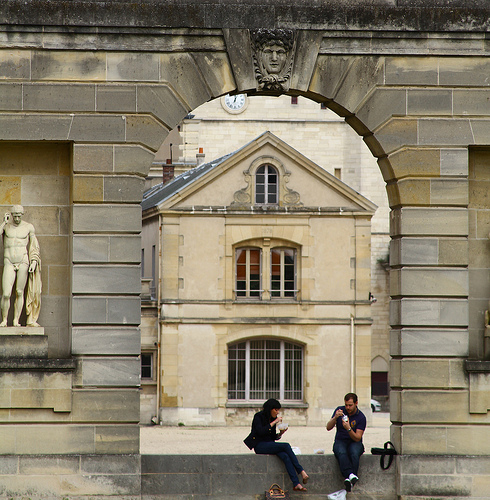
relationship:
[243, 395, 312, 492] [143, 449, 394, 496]
person sitting on step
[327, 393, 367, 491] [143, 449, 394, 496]
man sitting on step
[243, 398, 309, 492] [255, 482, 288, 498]
person has handbag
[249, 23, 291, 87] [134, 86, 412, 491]
face above archway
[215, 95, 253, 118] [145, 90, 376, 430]
clock on front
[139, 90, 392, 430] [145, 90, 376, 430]
building has front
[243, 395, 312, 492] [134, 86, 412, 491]
person sitting under archway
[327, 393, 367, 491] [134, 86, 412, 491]
man sitting under archway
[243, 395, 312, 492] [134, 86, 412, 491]
person under archway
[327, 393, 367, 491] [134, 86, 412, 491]
man under archway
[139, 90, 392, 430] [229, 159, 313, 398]
building has windows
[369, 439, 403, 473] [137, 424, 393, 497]
bag on ground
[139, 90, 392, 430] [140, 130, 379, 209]
building has arch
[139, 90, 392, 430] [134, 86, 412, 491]
building behind archway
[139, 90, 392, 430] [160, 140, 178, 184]
building has chimney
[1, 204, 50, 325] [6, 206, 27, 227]
statue has head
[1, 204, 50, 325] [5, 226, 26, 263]
statue has chest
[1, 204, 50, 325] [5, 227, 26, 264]
statue has torso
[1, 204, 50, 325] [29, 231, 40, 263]
statue has arm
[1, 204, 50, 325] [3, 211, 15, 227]
statue has left hand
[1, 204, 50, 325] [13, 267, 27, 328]
statue has left leg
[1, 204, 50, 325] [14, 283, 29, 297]
statue has left knee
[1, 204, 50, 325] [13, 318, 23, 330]
statue has left foot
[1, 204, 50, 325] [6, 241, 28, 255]
statue has abs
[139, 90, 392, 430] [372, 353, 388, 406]
building has door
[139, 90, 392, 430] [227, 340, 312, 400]
building has window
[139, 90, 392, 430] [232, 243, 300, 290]
building has window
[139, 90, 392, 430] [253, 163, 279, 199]
building has window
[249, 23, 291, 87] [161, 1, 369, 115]
face on top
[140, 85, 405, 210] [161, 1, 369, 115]
arch has top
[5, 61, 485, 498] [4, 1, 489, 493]
bricks on wall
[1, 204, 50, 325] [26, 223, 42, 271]
statue has arm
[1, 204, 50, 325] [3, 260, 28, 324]
statue has legs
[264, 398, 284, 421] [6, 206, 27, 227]
woman has head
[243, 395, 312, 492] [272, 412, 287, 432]
person eating ice cream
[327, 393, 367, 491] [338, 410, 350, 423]
man eating ice cream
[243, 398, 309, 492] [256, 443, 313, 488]
person sitting cross legged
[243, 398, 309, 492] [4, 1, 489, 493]
person on wall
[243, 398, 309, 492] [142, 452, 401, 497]
person sitting on wall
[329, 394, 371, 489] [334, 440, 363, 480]
man sitting cross legged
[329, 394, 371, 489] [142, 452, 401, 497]
man on wall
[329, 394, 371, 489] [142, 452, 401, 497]
man sitting on wall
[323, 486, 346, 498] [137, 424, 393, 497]
bag on ground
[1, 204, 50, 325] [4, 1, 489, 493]
statue in wall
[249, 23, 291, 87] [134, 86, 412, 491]
face in archway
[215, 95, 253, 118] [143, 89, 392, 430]
clock built into face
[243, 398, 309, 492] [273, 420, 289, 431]
person eating out of container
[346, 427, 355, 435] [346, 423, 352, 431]
watch on wrist